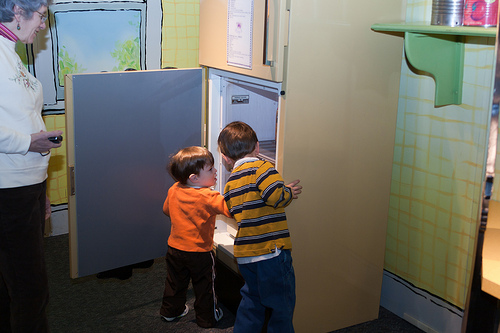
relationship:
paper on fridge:
[224, 0, 252, 69] [192, 0, 408, 150]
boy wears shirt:
[211, 115, 303, 323] [225, 160, 296, 253]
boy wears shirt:
[164, 141, 230, 321] [160, 173, 226, 254]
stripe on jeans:
[207, 245, 235, 327] [230, 248, 298, 332]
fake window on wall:
[47, 8, 145, 77] [51, 1, 202, 68]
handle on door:
[258, 2, 272, 66] [189, 0, 284, 72]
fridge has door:
[189, 3, 401, 83] [189, 0, 284, 72]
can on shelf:
[460, 0, 496, 25] [373, 20, 493, 37]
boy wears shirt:
[159, 143, 235, 329] [165, 189, 225, 250]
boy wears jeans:
[215, 118, 307, 332] [239, 254, 302, 331]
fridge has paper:
[61, 0, 409, 333] [224, 0, 257, 64]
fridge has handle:
[61, 0, 409, 333] [260, 7, 273, 64]